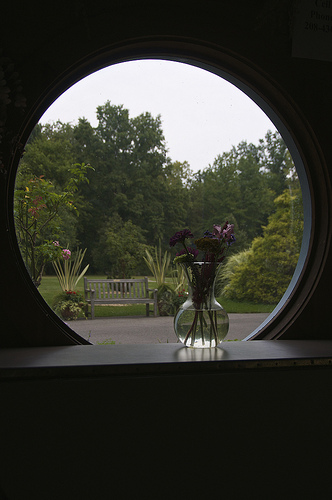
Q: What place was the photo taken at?
A: It was taken at the forest.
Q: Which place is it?
A: It is a forest.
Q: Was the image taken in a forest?
A: Yes, it was taken in a forest.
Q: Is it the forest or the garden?
A: It is the forest.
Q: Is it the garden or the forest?
A: It is the forest.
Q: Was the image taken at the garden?
A: No, the picture was taken in the forest.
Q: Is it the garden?
A: No, it is the forest.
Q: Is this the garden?
A: No, it is the forest.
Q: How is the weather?
A: It is cloudy.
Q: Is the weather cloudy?
A: Yes, it is cloudy.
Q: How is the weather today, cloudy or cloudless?
A: It is cloudy.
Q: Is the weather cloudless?
A: No, it is cloudy.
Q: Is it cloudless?
A: No, it is cloudy.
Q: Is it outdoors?
A: Yes, it is outdoors.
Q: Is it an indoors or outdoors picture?
A: It is outdoors.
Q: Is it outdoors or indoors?
A: It is outdoors.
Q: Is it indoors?
A: No, it is outdoors.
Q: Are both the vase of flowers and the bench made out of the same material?
A: No, the vase is made of glass and the bench is made of wood.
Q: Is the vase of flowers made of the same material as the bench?
A: No, the vase is made of glass and the bench is made of wood.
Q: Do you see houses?
A: No, there are no houses.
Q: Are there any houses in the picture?
A: No, there are no houses.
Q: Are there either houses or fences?
A: No, there are no houses or fences.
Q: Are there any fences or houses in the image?
A: No, there are no houses or fences.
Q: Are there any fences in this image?
A: No, there are no fences.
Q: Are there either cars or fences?
A: No, there are no fences or cars.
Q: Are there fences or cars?
A: No, there are no fences or cars.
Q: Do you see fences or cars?
A: No, there are no fences or cars.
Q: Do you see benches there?
A: Yes, there is a bench.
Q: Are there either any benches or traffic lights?
A: Yes, there is a bench.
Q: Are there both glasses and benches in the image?
A: No, there is a bench but no glasses.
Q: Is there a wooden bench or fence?
A: Yes, there is a wood bench.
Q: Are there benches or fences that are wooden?
A: Yes, the bench is wooden.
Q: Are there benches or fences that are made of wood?
A: Yes, the bench is made of wood.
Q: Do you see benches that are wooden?
A: Yes, there is a wood bench.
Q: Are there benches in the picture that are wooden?
A: Yes, there is a bench that is wooden.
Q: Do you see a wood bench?
A: Yes, there is a bench that is made of wood.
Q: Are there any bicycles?
A: No, there are no bicycles.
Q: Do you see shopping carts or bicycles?
A: No, there are no bicycles or shopping carts.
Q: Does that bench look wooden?
A: Yes, the bench is wooden.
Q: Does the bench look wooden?
A: Yes, the bench is wooden.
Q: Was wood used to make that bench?
A: Yes, the bench is made of wood.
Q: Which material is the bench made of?
A: The bench is made of wood.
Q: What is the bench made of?
A: The bench is made of wood.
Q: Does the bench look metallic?
A: No, the bench is wooden.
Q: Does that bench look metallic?
A: No, the bench is wooden.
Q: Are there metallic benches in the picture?
A: No, there is a bench but it is wooden.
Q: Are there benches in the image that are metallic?
A: No, there is a bench but it is wooden.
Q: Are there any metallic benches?
A: No, there is a bench but it is wooden.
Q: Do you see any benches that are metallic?
A: No, there is a bench but it is wooden.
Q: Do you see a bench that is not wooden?
A: No, there is a bench but it is wooden.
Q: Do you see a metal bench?
A: No, there is a bench but it is made of wood.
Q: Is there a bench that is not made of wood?
A: No, there is a bench but it is made of wood.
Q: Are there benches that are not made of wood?
A: No, there is a bench but it is made of wood.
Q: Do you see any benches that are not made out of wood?
A: No, there is a bench but it is made of wood.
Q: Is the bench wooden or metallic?
A: The bench is wooden.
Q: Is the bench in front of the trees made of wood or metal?
A: The bench is made of wood.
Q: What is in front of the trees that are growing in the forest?
A: The bench is in front of the trees.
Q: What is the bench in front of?
A: The bench is in front of the trees.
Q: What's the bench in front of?
A: The bench is in front of the trees.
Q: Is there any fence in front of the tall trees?
A: No, there is a bench in front of the trees.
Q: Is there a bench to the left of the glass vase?
A: Yes, there is a bench to the left of the vase.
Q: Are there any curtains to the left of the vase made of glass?
A: No, there is a bench to the left of the vase.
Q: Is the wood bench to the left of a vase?
A: Yes, the bench is to the left of a vase.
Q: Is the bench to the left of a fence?
A: No, the bench is to the left of a vase.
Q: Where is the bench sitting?
A: The bench is sitting in the garden.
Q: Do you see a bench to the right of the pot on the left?
A: Yes, there is a bench to the right of the pot.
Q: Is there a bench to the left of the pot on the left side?
A: No, the bench is to the right of the pot.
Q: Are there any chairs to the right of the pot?
A: No, there is a bench to the right of the pot.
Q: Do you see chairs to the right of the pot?
A: No, there is a bench to the right of the pot.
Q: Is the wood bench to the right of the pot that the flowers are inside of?
A: Yes, the bench is to the right of the pot.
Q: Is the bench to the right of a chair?
A: No, the bench is to the right of the pot.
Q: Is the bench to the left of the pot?
A: No, the bench is to the right of the pot.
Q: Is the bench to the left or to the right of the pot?
A: The bench is to the right of the pot.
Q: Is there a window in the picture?
A: Yes, there is a window.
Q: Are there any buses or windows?
A: Yes, there is a window.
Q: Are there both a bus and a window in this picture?
A: No, there is a window but no buses.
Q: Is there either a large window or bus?
A: Yes, there is a large window.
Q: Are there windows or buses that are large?
A: Yes, the window is large.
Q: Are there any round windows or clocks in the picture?
A: Yes, there is a round window.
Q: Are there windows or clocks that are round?
A: Yes, the window is round.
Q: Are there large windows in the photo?
A: Yes, there is a large window.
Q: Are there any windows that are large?
A: Yes, there is a window that is large.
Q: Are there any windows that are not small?
A: Yes, there is a large window.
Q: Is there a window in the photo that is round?
A: Yes, there is a round window.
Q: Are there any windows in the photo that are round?
A: Yes, there is a window that is round.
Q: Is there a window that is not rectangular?
A: Yes, there is a round window.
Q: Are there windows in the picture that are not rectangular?
A: Yes, there is a round window.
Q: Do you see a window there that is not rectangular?
A: Yes, there is a round window.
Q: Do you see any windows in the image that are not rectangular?
A: Yes, there is a round window.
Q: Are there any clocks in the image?
A: No, there are no clocks.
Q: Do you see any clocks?
A: No, there are no clocks.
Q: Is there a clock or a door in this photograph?
A: No, there are no clocks or doors.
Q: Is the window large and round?
A: Yes, the window is large and round.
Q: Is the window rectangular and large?
A: No, the window is large but round.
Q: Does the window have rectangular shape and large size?
A: No, the window is large but round.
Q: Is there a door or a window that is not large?
A: No, there is a window but it is large.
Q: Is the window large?
A: Yes, the window is large.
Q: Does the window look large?
A: Yes, the window is large.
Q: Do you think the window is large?
A: Yes, the window is large.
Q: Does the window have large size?
A: Yes, the window is large.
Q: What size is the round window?
A: The window is large.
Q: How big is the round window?
A: The window is large.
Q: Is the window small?
A: No, the window is large.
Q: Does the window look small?
A: No, the window is large.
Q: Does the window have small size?
A: No, the window is large.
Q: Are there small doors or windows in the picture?
A: No, there is a window but it is large.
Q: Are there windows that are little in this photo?
A: No, there is a window but it is large.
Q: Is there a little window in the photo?
A: No, there is a window but it is large.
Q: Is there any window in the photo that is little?
A: No, there is a window but it is large.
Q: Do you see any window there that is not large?
A: No, there is a window but it is large.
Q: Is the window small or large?
A: The window is large.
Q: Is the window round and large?
A: Yes, the window is round and large.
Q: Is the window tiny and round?
A: No, the window is round but large.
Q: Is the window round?
A: Yes, the window is round.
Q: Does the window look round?
A: Yes, the window is round.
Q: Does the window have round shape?
A: Yes, the window is round.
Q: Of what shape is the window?
A: The window is round.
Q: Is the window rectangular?
A: No, the window is round.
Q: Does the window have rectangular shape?
A: No, the window is round.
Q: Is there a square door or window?
A: No, there is a window but it is round.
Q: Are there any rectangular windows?
A: No, there is a window but it is round.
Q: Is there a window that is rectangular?
A: No, there is a window but it is round.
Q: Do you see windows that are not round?
A: No, there is a window but it is round.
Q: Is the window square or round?
A: The window is round.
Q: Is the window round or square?
A: The window is round.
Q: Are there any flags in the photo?
A: No, there are no flags.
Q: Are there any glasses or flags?
A: No, there are no flags or glasses.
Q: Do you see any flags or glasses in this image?
A: No, there are no flags or glasses.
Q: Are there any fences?
A: No, there are no fences.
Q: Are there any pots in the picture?
A: Yes, there is a pot.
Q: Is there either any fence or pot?
A: Yes, there is a pot.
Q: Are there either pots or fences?
A: Yes, there is a pot.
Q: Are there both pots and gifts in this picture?
A: No, there is a pot but no gifts.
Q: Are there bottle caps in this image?
A: No, there are no bottle caps.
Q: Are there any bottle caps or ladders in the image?
A: No, there are no bottle caps or ladders.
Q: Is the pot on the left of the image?
A: Yes, the pot is on the left of the image.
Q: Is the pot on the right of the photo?
A: No, the pot is on the left of the image.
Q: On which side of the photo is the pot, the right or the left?
A: The pot is on the left of the image.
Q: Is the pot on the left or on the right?
A: The pot is on the left of the image.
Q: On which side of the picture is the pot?
A: The pot is on the left of the image.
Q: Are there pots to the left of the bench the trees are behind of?
A: Yes, there is a pot to the left of the bench.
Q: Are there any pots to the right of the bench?
A: No, the pot is to the left of the bench.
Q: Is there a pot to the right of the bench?
A: No, the pot is to the left of the bench.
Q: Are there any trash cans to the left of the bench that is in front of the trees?
A: No, there is a pot to the left of the bench.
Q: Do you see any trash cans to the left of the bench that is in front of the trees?
A: No, there is a pot to the left of the bench.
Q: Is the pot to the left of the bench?
A: Yes, the pot is to the left of the bench.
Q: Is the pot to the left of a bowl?
A: No, the pot is to the left of the bench.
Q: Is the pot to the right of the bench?
A: No, the pot is to the left of the bench.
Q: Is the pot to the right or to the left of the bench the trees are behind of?
A: The pot is to the left of the bench.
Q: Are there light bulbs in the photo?
A: No, there are no light bulbs.